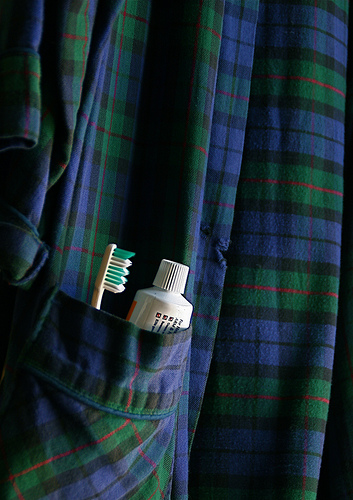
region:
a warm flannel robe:
[0, 0, 348, 497]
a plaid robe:
[0, 0, 348, 498]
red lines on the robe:
[0, 1, 344, 499]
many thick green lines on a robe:
[2, 5, 348, 498]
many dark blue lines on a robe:
[0, 3, 350, 497]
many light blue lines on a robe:
[5, 2, 347, 497]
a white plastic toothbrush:
[83, 234, 142, 329]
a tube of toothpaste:
[117, 253, 199, 341]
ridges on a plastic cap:
[142, 255, 199, 301]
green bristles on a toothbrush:
[100, 243, 143, 293]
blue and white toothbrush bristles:
[94, 234, 132, 306]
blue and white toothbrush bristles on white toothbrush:
[87, 238, 136, 308]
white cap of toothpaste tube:
[149, 252, 196, 293]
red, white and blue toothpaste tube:
[133, 284, 192, 328]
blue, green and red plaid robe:
[13, 5, 121, 126]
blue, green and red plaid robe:
[96, 15, 230, 233]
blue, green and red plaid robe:
[232, 13, 339, 227]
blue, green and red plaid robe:
[200, 251, 335, 486]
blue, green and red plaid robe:
[11, 334, 227, 480]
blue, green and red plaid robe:
[14, 96, 235, 239]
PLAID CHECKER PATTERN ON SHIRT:
[214, 310, 348, 494]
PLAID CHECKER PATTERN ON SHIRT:
[166, 338, 285, 490]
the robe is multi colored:
[49, 38, 289, 225]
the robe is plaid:
[227, 239, 329, 414]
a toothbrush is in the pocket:
[99, 241, 131, 329]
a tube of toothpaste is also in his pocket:
[128, 245, 208, 345]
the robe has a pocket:
[25, 278, 204, 468]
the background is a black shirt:
[147, 41, 196, 143]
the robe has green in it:
[251, 156, 327, 212]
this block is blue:
[228, 31, 258, 68]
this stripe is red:
[273, 171, 338, 201]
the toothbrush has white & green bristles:
[92, 231, 133, 315]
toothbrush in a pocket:
[90, 241, 133, 319]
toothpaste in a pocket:
[127, 252, 193, 340]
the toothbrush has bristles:
[85, 238, 134, 313]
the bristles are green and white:
[100, 244, 132, 292]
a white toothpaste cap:
[151, 255, 191, 296]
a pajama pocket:
[1, 284, 185, 496]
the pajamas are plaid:
[1, 3, 346, 497]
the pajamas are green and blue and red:
[1, 2, 338, 495]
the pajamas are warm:
[2, 2, 343, 495]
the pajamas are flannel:
[3, 0, 347, 494]